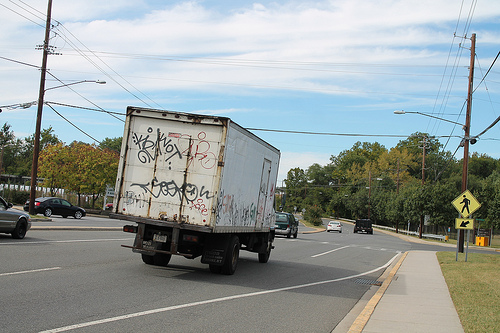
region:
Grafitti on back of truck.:
[130, 124, 207, 209]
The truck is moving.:
[112, 103, 281, 283]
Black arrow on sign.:
[452, 217, 474, 229]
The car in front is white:
[323, 217, 343, 234]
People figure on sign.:
[448, 189, 483, 216]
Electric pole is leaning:
[27, 1, 53, 213]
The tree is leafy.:
[37, 139, 118, 211]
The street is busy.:
[1, 190, 408, 331]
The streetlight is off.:
[391, 105, 467, 131]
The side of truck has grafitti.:
[215, 171, 278, 226]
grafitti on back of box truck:
[105, 88, 226, 238]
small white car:
[322, 210, 351, 242]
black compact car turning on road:
[24, 190, 97, 225]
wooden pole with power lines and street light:
[3, 0, 98, 227]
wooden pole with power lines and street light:
[390, 13, 497, 284]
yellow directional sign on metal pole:
[438, 169, 489, 277]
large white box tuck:
[90, 78, 315, 295]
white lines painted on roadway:
[306, 233, 390, 331]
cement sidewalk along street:
[348, 238, 458, 328]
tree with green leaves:
[360, 146, 479, 232]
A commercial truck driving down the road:
[112, 94, 281, 284]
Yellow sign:
[442, 185, 485, 246]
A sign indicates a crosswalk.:
[443, 187, 488, 258]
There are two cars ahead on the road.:
[317, 212, 384, 244]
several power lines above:
[340, 91, 498, 153]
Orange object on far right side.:
[472, 231, 496, 253]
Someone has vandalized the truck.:
[133, 118, 212, 198]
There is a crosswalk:
[302, 234, 399, 259]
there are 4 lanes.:
[32, 208, 114, 331]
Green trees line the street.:
[292, 154, 421, 206]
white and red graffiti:
[130, 117, 212, 221]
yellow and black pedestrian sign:
[450, 187, 477, 228]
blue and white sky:
[0, 0, 497, 155]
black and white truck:
[110, 110, 280, 270]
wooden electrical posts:
[454, 31, 478, 255]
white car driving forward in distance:
[325, 220, 343, 230]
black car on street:
[24, 195, 84, 220]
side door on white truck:
[257, 155, 272, 231]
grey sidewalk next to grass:
[345, 241, 497, 331]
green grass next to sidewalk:
[437, 248, 498, 331]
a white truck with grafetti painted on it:
[84, 125, 293, 287]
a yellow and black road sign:
[450, 187, 482, 252]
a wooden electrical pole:
[8, 13, 73, 222]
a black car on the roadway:
[26, 196, 82, 220]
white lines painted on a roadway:
[305, 240, 372, 284]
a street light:
[27, 71, 114, 105]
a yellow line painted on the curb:
[353, 242, 415, 331]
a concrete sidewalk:
[380, 244, 443, 331]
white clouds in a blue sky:
[177, 18, 402, 93]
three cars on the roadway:
[248, 202, 383, 242]